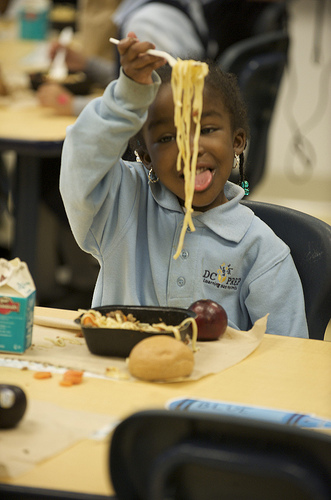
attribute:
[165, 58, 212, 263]
noodles — in the air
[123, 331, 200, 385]
bread — golden, dinner roll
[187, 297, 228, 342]
fruit — dark red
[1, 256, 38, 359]
milk carton — blue, white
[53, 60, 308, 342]
shirt — blue, light blue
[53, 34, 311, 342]
girl — eating, little, sitting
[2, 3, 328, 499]
cafeteria — in school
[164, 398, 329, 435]
crayon — blue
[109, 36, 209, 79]
fork — plastic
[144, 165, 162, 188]
earring — pretty, hoop, gold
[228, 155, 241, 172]
earring — pretty, hoop, gold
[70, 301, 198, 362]
container — black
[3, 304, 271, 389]
paper towel — brown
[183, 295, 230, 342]
apple — dark red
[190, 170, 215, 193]
tongue — sticking out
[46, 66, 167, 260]
sleeve — long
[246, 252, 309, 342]
sleeve — long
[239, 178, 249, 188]
bead — pale blue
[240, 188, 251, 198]
bead — pale blue